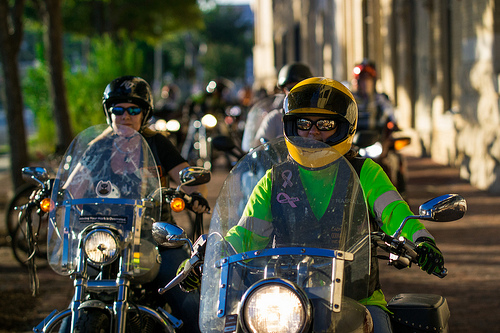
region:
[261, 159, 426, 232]
A fluorescent yellow shirt with a black vest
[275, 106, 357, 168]
A man wearing a yellow helmet with reflective sunglasses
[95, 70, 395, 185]
A train of motorcycles drive down the road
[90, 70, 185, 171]
A woman with sunglasses and a black helmet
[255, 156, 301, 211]
Ribbons on a black vest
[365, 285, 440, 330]
Saddlebags for the motorcycle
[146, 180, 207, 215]
Yellow lights on the handlebars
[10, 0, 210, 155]
Trees line the road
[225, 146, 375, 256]
A bug splattered windshield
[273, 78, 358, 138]
Visor up on a yellow helmet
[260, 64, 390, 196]
Black and white helmet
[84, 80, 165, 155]
Black helmet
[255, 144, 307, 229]
breast cancer patches on woman's vest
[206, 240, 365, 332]
Headlight on closest motorcycle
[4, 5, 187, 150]
Two trees behind the women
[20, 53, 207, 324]
Woman in black t shirt and her motorcycle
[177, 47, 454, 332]
Motorcycle and woman in yellow and black helmet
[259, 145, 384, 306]
Woman's vest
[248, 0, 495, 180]
Building behind the cyclists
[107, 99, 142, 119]
sunglasses with blue lenses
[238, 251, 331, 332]
light on front of motorcycle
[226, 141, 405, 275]
green shirt on driver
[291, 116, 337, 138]
sunglasses on driver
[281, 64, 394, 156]
yellow helmet with clear visor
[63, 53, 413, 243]
many drivers riding their bikes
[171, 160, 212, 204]
rear view mirror on side of bike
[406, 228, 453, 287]
green and black gloves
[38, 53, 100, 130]
brown tree trunk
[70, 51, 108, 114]
green tree in background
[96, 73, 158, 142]
helmet and sunglasses on woman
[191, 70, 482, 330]
Person riding a motorcycle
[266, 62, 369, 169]
Yellow motorcycle helmet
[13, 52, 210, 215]
Woman riding a motorcycle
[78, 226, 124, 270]
Motorcycle headlight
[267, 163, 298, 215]
Pink breast cancer awareness patches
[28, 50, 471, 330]
Participants in a motorcycle rally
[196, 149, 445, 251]
Green safety vest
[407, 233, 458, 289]
Riding glove for protection of hands in case of an accident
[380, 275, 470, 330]
Black leather side bag to safely carry belongings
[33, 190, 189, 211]
Motorcycle turn signals to alert automobile drivers of turning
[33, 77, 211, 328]
woman on motorcycle wearing helmet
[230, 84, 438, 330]
person on motorcycle wearing bright jacket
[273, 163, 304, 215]
breast cancer awareness ribbons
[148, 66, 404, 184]
people in the background riding motorcycles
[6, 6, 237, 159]
blurry trees in the background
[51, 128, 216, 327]
motorcycle with lights on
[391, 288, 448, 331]
motorcycle hatch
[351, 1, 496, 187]
out of focus buildings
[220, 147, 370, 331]
motorcycle sheild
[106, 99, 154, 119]
polarized sunglasses